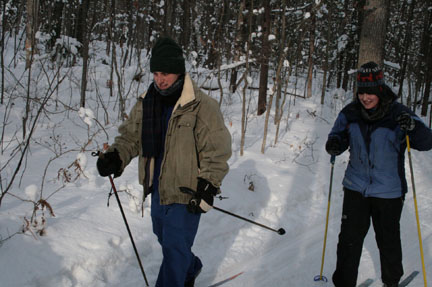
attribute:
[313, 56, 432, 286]
woman — on skis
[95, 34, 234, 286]
man — on skis, walking, cross country skiing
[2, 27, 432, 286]
ground — snow covered, white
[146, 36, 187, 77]
hat — black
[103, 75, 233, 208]
jacket — tan, brown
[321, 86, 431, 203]
jacket — blue, black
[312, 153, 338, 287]
ski stick — yellow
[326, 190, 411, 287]
pants — black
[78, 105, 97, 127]
snow — white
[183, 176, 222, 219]
glove — black, white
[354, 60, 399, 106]
hat — black red, white, red gray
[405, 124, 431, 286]
ski pole — yellow, black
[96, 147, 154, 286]
ski pole — black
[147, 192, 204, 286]
jeans — blue